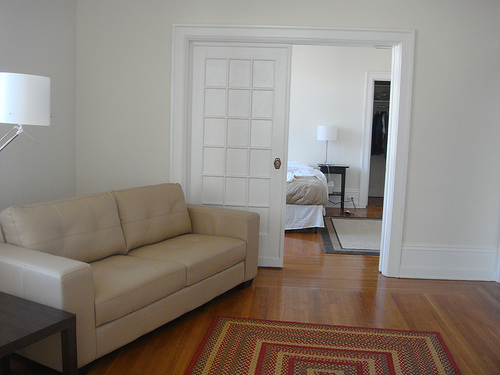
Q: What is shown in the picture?
A: A living room.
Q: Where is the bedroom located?
A: Through the door.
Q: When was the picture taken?
A: At daytime.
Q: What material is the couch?
A: Leather.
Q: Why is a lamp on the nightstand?
A: For lighting.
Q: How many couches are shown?
A: One.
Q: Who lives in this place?
A: A tidy person.